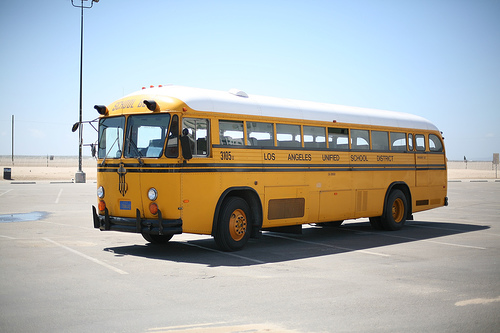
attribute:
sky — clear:
[139, 10, 454, 87]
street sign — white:
[484, 148, 499, 177]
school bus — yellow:
[110, 102, 439, 158]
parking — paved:
[11, 238, 174, 321]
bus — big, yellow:
[97, 87, 463, 240]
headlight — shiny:
[146, 187, 160, 201]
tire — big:
[219, 202, 256, 244]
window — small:
[212, 110, 253, 149]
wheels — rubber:
[369, 184, 414, 235]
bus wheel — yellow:
[220, 200, 318, 259]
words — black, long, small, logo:
[261, 144, 401, 167]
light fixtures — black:
[134, 97, 161, 110]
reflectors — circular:
[142, 207, 162, 215]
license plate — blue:
[117, 204, 139, 213]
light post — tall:
[74, 5, 92, 184]